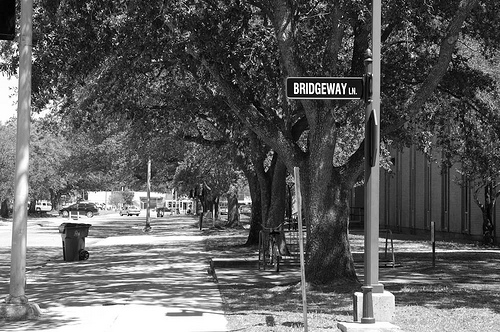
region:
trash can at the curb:
[58, 216, 95, 263]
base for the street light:
[0, 297, 38, 317]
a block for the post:
[349, 285, 398, 322]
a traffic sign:
[288, 67, 380, 164]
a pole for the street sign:
[356, 46, 379, 322]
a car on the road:
[112, 203, 144, 220]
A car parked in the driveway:
[57, 197, 101, 221]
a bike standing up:
[260, 215, 292, 276]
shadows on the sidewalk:
[118, 242, 187, 329]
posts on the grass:
[323, 278, 437, 330]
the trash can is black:
[64, 237, 72, 246]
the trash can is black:
[62, 228, 79, 248]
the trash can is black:
[67, 239, 77, 250]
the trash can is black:
[76, 230, 83, 242]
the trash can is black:
[68, 228, 80, 258]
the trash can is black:
[76, 232, 83, 253]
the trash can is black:
[73, 234, 78, 254]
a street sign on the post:
[281, 72, 373, 101]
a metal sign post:
[359, 0, 387, 294]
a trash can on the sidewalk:
[53, 215, 105, 270]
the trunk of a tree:
[290, 164, 361, 290]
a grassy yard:
[224, 257, 497, 329]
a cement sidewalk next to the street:
[3, 200, 230, 330]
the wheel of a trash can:
[76, 245, 96, 263]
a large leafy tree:
[1, 0, 496, 290]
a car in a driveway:
[52, 198, 103, 219]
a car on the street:
[113, 201, 145, 218]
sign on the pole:
[271, 63, 375, 110]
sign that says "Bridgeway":
[281, 66, 366, 116]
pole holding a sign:
[338, 141, 399, 217]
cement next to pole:
[129, 261, 187, 313]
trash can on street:
[48, 208, 110, 275]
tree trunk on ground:
[290, 190, 358, 257]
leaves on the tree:
[87, 71, 162, 120]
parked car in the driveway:
[56, 186, 109, 220]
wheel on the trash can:
[78, 246, 98, 263]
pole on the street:
[0, 147, 60, 219]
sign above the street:
[274, 62, 365, 116]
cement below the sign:
[118, 259, 183, 316]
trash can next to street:
[41, 215, 99, 275]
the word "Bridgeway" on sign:
[274, 67, 360, 110]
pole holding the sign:
[326, 145, 403, 255]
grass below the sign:
[424, 301, 455, 323]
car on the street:
[115, 196, 143, 225]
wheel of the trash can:
[77, 248, 94, 265]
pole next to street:
[6, 104, 59, 274]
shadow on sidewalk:
[133, 261, 191, 321]